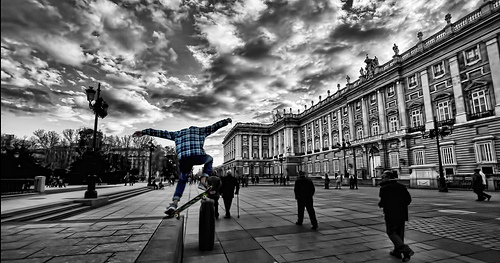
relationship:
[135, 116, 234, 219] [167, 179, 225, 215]
he uses board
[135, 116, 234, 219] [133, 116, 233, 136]
boy has hands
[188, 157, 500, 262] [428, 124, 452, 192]
street has light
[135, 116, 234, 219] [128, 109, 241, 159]
boy has shirt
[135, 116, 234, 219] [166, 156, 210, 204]
boy has trousers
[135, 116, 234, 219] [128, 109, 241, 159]
boy has jacket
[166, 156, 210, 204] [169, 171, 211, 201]
pants turned up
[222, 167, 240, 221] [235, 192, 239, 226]
man has cane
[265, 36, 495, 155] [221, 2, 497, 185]
pillars on building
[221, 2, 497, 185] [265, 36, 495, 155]
building has pillars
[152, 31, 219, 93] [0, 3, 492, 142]
sun behind clouds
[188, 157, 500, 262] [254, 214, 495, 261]
walkway has stones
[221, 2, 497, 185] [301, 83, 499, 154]
building has windows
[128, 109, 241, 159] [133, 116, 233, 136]
shirt has sleeves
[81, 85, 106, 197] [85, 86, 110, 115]
pole has lamp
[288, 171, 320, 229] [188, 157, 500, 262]
man on road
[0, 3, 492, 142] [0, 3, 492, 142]
sky has sky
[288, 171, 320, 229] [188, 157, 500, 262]
person in street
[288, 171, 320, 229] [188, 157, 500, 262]
man in street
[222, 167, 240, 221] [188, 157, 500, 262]
person in street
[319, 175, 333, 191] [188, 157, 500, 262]
person in street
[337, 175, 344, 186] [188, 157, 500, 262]
person in street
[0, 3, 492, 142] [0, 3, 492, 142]
sky has clouds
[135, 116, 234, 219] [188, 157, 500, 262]
person in road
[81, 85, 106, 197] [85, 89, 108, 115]
post has lamp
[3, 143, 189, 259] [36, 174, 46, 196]
sidewalk has can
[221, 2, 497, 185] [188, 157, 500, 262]
building near street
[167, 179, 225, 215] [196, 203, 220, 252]
board on board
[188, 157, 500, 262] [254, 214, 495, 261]
street has pattern